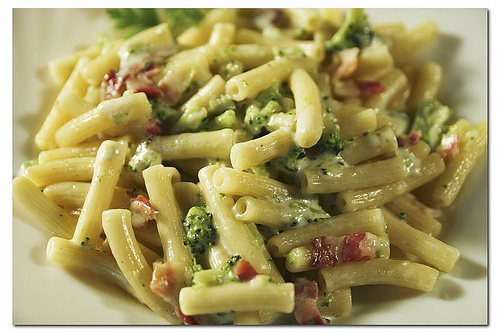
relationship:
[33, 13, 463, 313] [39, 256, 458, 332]
salad on plate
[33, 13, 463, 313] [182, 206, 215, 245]
salad has boccoli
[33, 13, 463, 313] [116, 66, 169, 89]
salad has bacon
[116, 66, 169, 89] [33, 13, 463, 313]
bacon in salad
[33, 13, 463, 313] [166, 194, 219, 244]
salad has broccoli